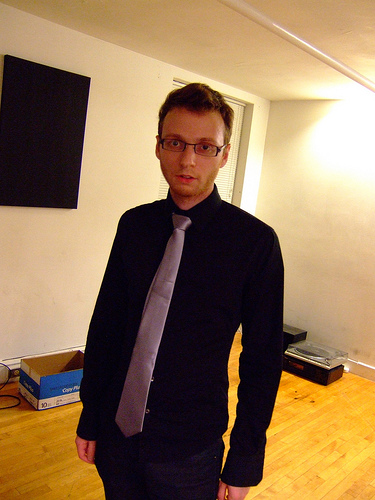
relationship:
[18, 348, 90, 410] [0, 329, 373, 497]
box on floor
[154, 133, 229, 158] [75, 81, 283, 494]
glasses on man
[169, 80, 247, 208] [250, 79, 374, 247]
window on wall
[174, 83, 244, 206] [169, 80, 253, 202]
blinds on window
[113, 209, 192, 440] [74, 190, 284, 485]
tie on black shirt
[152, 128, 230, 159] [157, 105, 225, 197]
glasses on face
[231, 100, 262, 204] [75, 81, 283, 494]
door behind man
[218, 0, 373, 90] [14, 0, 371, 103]
tube below ceiling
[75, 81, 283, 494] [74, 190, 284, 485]
man wearing black shirt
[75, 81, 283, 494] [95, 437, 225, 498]
man wearing jeans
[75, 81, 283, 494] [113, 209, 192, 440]
man wearing tie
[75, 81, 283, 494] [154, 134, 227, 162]
man wearing glasses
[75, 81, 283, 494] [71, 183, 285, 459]
man wearing shirt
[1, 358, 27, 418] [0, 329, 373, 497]
black cord on floor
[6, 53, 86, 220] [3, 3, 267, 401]
rectangle hanging on a wall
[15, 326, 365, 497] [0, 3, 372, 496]
floors in room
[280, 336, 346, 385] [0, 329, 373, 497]
record player in floor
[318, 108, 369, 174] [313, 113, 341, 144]
light shining on wall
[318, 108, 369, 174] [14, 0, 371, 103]
light shining on ceiling